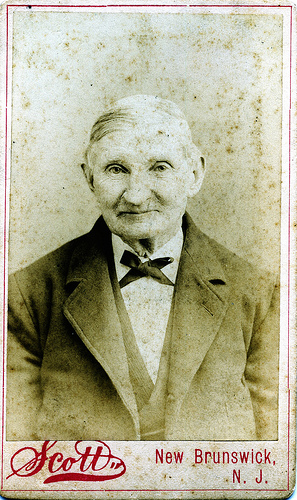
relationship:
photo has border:
[9, 11, 288, 497] [5, 5, 290, 486]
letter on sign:
[192, 448, 271, 464] [7, 6, 289, 490]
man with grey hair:
[9, 94, 285, 438] [84, 95, 201, 166]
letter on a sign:
[192, 448, 271, 464] [7, 6, 289, 490]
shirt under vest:
[113, 235, 185, 374] [104, 230, 174, 440]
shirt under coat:
[113, 235, 185, 374] [8, 213, 277, 441]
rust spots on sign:
[145, 463, 219, 493] [7, 6, 289, 490]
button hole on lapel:
[195, 295, 213, 329] [178, 224, 245, 421]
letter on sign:
[222, 448, 233, 464] [2, 434, 277, 493]